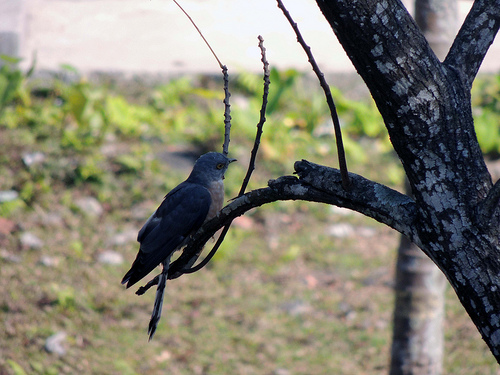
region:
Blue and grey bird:
[118, 150, 240, 283]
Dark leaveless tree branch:
[264, 147, 390, 226]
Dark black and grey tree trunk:
[359, 139, 499, 354]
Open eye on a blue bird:
[210, 155, 229, 175]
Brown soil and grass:
[5, 267, 102, 338]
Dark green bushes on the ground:
[27, 75, 147, 157]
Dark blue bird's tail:
[115, 224, 174, 291]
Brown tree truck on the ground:
[376, 255, 448, 372]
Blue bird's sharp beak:
[222, 155, 239, 167]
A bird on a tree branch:
[115, 138, 241, 339]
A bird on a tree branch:
[115, 145, 245, 345]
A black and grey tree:
[94, 0, 499, 312]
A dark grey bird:
[103, 132, 234, 314]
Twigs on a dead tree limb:
[192, 8, 347, 168]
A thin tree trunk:
[377, 230, 445, 370]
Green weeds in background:
[21, 64, 221, 150]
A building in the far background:
[23, 22, 280, 73]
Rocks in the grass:
[64, 195, 123, 270]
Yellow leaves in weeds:
[274, 114, 307, 144]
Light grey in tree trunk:
[377, 35, 472, 263]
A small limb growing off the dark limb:
[443, 15, 498, 86]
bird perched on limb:
[120, 141, 231, 346]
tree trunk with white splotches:
[305, 2, 498, 357]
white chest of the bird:
[205, 176, 224, 222]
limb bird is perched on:
[148, 150, 431, 279]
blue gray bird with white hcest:
[120, 142, 238, 334]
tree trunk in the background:
[382, 180, 451, 374]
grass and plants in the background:
[10, 63, 492, 372]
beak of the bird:
[229, 153, 236, 168]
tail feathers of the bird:
[120, 253, 148, 294]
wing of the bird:
[122, 188, 199, 283]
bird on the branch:
[116, 151, 240, 283]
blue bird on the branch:
[121, 148, 236, 287]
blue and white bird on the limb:
[121, 149, 238, 290]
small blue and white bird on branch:
[111, 148, 240, 287]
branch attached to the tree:
[273, 5, 344, 170]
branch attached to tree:
[246, 38, 274, 191]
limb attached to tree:
[443, 0, 498, 64]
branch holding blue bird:
[99, 130, 425, 300]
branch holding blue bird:
[102, 117, 433, 290]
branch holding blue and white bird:
[119, 143, 419, 293]